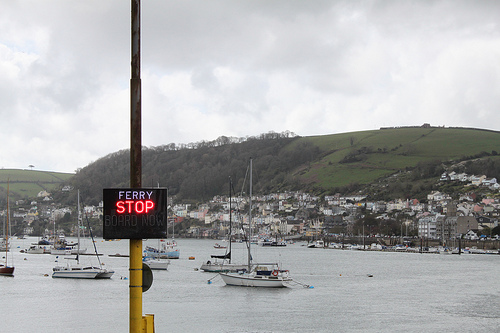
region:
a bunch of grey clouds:
[216, 8, 307, 63]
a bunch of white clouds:
[177, 83, 237, 118]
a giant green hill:
[347, 120, 434, 175]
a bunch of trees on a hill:
[340, 138, 370, 163]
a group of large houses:
[272, 193, 318, 226]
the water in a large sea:
[318, 250, 433, 328]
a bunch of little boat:
[197, 219, 288, 301]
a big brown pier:
[334, 225, 398, 257]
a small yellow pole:
[113, 243, 165, 327]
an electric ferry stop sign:
[86, 186, 177, 244]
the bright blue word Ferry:
[117, 188, 153, 200]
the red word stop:
[114, 201, 159, 211]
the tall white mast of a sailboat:
[75, 183, 85, 270]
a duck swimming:
[168, 199, 177, 246]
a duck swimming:
[247, 156, 257, 276]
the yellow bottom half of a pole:
[126, 238, 143, 328]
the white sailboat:
[219, 156, 284, 291]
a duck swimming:
[49, 186, 110, 282]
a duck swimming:
[48, 213, 83, 253]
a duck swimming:
[146, 256, 168, 273]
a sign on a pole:
[84, 154, 210, 324]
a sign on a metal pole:
[82, 158, 225, 300]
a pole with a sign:
[79, 147, 182, 313]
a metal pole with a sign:
[79, 151, 199, 286]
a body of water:
[353, 249, 414, 327]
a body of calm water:
[294, 243, 436, 328]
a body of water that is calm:
[343, 254, 497, 306]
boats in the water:
[157, 178, 309, 327]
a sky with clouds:
[204, 4, 409, 89]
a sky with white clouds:
[269, 29, 497, 144]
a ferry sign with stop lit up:
[100, 175, 172, 243]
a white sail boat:
[213, 146, 312, 299]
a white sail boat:
[47, 177, 115, 292]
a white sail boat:
[196, 162, 253, 282]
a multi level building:
[410, 207, 475, 249]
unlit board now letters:
[96, 212, 168, 229]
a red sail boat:
[2, 187, 19, 277]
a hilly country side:
[8, 127, 495, 209]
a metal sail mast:
[246, 143, 254, 274]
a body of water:
[7, 223, 494, 330]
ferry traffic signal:
[101, 186, 167, 239]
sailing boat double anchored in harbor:
[205, 156, 314, 291]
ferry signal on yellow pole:
[105, 0, 167, 332]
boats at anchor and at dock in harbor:
[0, 156, 498, 331]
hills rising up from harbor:
[0, 123, 499, 237]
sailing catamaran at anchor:
[54, 188, 112, 279]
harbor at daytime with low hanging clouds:
[0, 0, 496, 332]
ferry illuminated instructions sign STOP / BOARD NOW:
[101, 185, 162, 236]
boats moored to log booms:
[21, 188, 179, 258]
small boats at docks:
[304, 239, 498, 257]